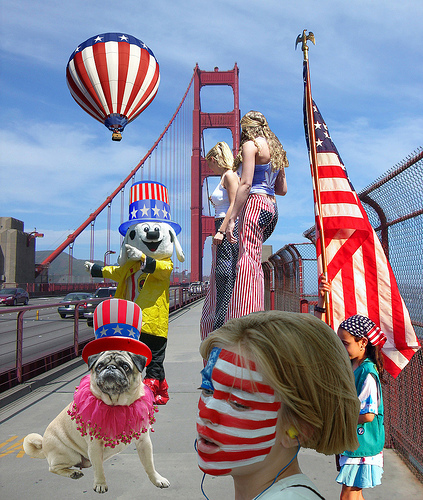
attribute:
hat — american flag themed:
[114, 171, 194, 235]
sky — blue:
[7, 6, 57, 207]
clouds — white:
[300, 7, 420, 84]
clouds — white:
[160, 5, 308, 81]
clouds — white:
[11, 118, 92, 249]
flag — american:
[285, 114, 420, 307]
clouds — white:
[11, 130, 85, 203]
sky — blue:
[10, 2, 414, 269]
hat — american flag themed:
[77, 297, 151, 370]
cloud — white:
[2, 4, 420, 303]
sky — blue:
[3, 2, 418, 298]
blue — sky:
[332, 55, 388, 101]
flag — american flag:
[328, 257, 387, 310]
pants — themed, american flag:
[223, 195, 275, 321]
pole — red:
[34, 65, 194, 277]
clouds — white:
[229, 29, 297, 92]